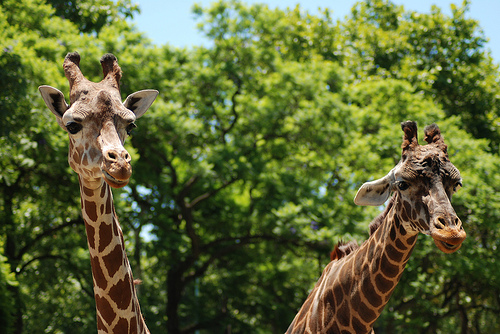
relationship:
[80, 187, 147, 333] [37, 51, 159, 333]
neck of giraffe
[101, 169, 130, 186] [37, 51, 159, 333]
mouth of giraffe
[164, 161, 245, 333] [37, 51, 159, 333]
tree behind giraffe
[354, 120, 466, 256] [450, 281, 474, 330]
head in front of tree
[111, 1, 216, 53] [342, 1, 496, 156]
sky over leaves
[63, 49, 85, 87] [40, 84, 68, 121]
horn above ear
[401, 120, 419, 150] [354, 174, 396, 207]
horn above ear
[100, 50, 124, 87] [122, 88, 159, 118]
horn above ear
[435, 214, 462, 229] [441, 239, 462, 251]
nose over mouth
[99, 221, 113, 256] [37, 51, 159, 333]
spot on giraffe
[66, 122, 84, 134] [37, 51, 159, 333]
eye on giraffe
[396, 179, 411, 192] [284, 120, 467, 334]
eye on giraffe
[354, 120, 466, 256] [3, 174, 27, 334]
face among tree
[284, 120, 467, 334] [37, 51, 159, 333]
giraffe beside giraffe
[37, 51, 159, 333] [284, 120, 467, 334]
giraffe on left of giraffe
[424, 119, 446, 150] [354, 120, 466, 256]
horn on head